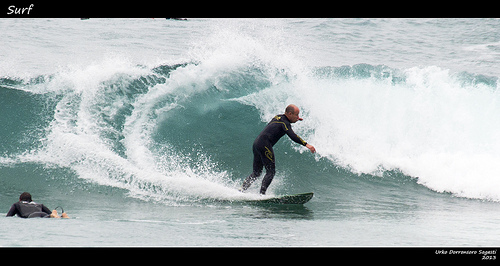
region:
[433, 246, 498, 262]
white caption and date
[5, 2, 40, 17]
white caption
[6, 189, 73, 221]
surfer wearing a black wet suit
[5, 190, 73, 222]
surfer paddling into the ocean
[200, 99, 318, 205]
surfer on a surfboard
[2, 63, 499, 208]
wave crashing in ocean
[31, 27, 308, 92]
whitecap on top of wave in ocean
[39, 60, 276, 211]
wake created by surfboard in water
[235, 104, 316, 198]
surfer wearing a black wetsuit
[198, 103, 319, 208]
surfer riding on a wave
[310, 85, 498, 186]
white caps on the waves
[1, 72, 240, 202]
large wave in the water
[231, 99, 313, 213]
man on a surfboard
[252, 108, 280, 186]
man wearing a black and gold suit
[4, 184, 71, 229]
person lying in the water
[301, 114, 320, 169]
hands are outstrected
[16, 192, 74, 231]
person lying flat on stomach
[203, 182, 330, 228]
surfboard in the water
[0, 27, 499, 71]
white foam in the water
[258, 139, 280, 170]
yellow stripe on the side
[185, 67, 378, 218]
he is wearing a wet suit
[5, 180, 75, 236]
he is lying on his board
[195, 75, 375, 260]
he is surfing a wave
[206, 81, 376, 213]
his arms are out for balance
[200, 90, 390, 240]
he is standing on his surfboard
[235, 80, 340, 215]
his wetsuit is black and yellow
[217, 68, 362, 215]
this man is wearing a black wetsuit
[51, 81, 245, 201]
a trail of water from his surfboard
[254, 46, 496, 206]
the wave is crashing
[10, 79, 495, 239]
the water is an ice blue color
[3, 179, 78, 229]
a man laying on the water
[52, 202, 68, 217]
a leash to the surfboard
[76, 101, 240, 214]
a large wake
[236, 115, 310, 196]
a yellow and black wetsuit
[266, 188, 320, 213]
the nose of a surfboard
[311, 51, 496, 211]
a large wave crashing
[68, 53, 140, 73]
a spray of water droplets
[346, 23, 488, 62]
ripples in the water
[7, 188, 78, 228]
man on his belly in the ocean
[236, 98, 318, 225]
man riding on his board in the waves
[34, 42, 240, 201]
trail of waves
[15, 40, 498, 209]
foamy white water from the waves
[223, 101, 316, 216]
man balancing on a board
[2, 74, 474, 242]
blue waves in the ocean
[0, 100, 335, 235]
two people in the ocean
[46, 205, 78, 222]
human feet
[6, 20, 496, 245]
choppy ocean water